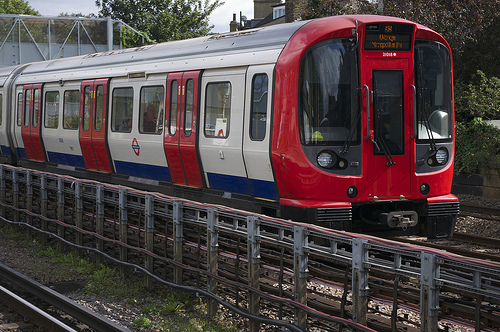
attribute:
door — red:
[78, 76, 114, 175]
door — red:
[20, 83, 48, 163]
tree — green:
[453, 1, 498, 116]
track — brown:
[385, 207, 499, 261]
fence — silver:
[1, 163, 499, 331]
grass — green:
[39, 247, 101, 294]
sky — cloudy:
[29, 0, 102, 16]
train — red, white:
[6, 12, 464, 233]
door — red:
[160, 74, 210, 192]